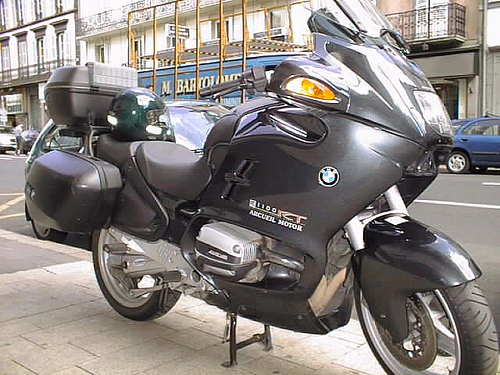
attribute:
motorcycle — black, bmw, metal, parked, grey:
[29, 0, 500, 374]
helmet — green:
[107, 85, 178, 143]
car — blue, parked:
[439, 115, 499, 174]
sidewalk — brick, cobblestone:
[0, 227, 458, 374]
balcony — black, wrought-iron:
[384, 4, 468, 53]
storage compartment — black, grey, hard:
[42, 60, 139, 131]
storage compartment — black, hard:
[25, 150, 124, 234]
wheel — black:
[350, 267, 499, 375]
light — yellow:
[282, 75, 339, 103]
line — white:
[415, 199, 499, 211]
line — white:
[482, 181, 499, 187]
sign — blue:
[135, 54, 298, 102]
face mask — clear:
[148, 107, 177, 142]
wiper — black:
[336, 1, 368, 37]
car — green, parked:
[23, 98, 235, 246]